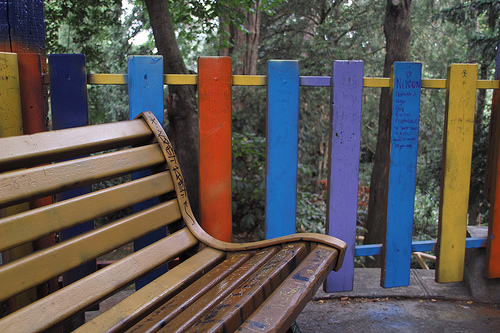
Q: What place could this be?
A: It is a patio.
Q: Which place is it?
A: It is a patio.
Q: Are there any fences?
A: Yes, there is a fence.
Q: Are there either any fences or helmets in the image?
A: Yes, there is a fence.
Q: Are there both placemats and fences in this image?
A: No, there is a fence but no placemats.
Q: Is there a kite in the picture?
A: No, there are no kites.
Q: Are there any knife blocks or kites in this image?
A: No, there are no kites or knife blocks.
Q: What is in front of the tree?
A: The fence is in front of the tree.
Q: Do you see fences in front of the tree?
A: Yes, there is a fence in front of the tree.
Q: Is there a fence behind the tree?
A: No, the fence is in front of the tree.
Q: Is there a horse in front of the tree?
A: No, there is a fence in front of the tree.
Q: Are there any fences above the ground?
A: Yes, there is a fence above the ground.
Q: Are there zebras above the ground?
A: No, there is a fence above the ground.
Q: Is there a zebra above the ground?
A: No, there is a fence above the ground.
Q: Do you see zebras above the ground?
A: No, there is a fence above the ground.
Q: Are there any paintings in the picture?
A: No, there are no paintings.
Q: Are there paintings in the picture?
A: No, there are no paintings.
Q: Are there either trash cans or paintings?
A: No, there are no paintings or trash cans.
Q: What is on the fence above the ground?
A: The graffiti is on the fence.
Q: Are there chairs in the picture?
A: No, there are no chairs.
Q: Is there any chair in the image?
A: No, there are no chairs.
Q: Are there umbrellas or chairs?
A: No, there are no chairs or umbrellas.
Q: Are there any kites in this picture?
A: No, there are no kites.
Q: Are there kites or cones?
A: No, there are no kites or cones.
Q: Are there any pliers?
A: No, there are no pliers.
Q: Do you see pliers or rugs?
A: No, there are no pliers or rugs.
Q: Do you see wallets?
A: No, there are no wallets.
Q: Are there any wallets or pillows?
A: No, there are no wallets or pillows.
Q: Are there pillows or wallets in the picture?
A: No, there are no wallets or pillows.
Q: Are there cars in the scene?
A: No, there are no cars.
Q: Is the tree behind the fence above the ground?
A: Yes, the tree is behind the fence.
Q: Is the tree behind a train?
A: No, the tree is behind the fence.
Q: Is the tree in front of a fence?
A: No, the tree is behind a fence.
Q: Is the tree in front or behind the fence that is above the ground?
A: The tree is behind the fence.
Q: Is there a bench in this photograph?
A: Yes, there is a bench.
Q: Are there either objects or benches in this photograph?
A: Yes, there is a bench.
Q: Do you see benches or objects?
A: Yes, there is a bench.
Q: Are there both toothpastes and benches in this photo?
A: No, there is a bench but no toothpastes.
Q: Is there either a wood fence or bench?
A: Yes, there is a wood bench.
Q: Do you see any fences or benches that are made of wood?
A: Yes, the bench is made of wood.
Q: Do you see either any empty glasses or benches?
A: Yes, there is an empty bench.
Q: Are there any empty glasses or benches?
A: Yes, there is an empty bench.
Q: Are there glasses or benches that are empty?
A: Yes, the bench is empty.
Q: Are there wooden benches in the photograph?
A: Yes, there is a wood bench.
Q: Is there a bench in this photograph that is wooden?
A: Yes, there is a bench that is wooden.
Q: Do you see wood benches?
A: Yes, there is a bench that is made of wood.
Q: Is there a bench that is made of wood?
A: Yes, there is a bench that is made of wood.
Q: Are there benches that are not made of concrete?
A: Yes, there is a bench that is made of wood.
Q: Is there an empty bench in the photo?
A: Yes, there is an empty bench.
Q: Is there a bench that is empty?
A: Yes, there is a bench that is empty.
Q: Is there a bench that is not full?
A: Yes, there is a empty bench.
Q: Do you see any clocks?
A: No, there are no clocks.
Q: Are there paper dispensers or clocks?
A: No, there are no clocks or paper dispensers.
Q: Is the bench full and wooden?
A: No, the bench is wooden but empty.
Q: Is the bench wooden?
A: Yes, the bench is wooden.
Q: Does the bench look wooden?
A: Yes, the bench is wooden.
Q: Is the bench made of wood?
A: Yes, the bench is made of wood.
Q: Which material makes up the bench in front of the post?
A: The bench is made of wood.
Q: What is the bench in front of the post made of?
A: The bench is made of wood.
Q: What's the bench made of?
A: The bench is made of wood.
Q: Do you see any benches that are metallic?
A: No, there is a bench but it is wooden.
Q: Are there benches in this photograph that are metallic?
A: No, there is a bench but it is wooden.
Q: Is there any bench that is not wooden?
A: No, there is a bench but it is wooden.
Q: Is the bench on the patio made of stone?
A: No, the bench is made of wood.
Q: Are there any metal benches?
A: No, there is a bench but it is made of wood.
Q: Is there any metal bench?
A: No, there is a bench but it is made of wood.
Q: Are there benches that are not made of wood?
A: No, there is a bench but it is made of wood.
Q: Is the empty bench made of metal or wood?
A: The bench is made of wood.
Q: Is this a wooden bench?
A: Yes, this is a wooden bench.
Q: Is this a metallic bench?
A: No, this is a wooden bench.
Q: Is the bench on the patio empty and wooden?
A: Yes, the bench is empty and wooden.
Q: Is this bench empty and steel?
A: No, the bench is empty but wooden.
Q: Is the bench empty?
A: Yes, the bench is empty.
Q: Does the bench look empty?
A: Yes, the bench is empty.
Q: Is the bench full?
A: No, the bench is empty.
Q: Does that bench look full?
A: No, the bench is empty.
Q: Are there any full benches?
A: No, there is a bench but it is empty.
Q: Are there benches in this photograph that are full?
A: No, there is a bench but it is empty.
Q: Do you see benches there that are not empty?
A: No, there is a bench but it is empty.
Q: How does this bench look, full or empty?
A: The bench is empty.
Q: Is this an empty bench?
A: Yes, this is an empty bench.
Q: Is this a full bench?
A: No, this is an empty bench.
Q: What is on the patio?
A: The bench is on the patio.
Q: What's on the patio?
A: The bench is on the patio.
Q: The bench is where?
A: The bench is on the patio.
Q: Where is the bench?
A: The bench is on the patio.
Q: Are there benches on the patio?
A: Yes, there is a bench on the patio.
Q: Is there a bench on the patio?
A: Yes, there is a bench on the patio.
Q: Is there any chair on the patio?
A: No, there is a bench on the patio.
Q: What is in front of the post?
A: The bench is in front of the post.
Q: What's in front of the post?
A: The bench is in front of the post.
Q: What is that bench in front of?
A: The bench is in front of the post.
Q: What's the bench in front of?
A: The bench is in front of the post.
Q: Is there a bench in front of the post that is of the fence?
A: Yes, there is a bench in front of the post.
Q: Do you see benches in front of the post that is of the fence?
A: Yes, there is a bench in front of the post.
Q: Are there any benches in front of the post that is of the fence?
A: Yes, there is a bench in front of the post.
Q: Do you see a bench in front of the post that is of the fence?
A: Yes, there is a bench in front of the post.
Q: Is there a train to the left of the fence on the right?
A: No, there is a bench to the left of the fence.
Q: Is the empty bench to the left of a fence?
A: Yes, the bench is to the left of a fence.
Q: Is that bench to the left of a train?
A: No, the bench is to the left of a fence.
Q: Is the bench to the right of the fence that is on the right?
A: No, the bench is to the left of the fence.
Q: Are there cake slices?
A: No, there are no cake slices.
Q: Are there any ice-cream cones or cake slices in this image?
A: No, there are no cake slices or ice-cream cones.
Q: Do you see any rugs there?
A: No, there are no rugs.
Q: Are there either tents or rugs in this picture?
A: No, there are no rugs or tents.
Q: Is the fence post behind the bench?
A: Yes, the post is behind the bench.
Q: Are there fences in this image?
A: Yes, there is a fence.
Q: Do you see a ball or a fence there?
A: Yes, there is a fence.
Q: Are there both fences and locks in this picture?
A: No, there is a fence but no locks.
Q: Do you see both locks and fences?
A: No, there is a fence but no locks.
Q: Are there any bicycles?
A: No, there are no bicycles.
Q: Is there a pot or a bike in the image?
A: No, there are no bikes or pots.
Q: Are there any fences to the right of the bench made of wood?
A: Yes, there is a fence to the right of the bench.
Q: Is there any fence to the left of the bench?
A: No, the fence is to the right of the bench.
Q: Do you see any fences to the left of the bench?
A: No, the fence is to the right of the bench.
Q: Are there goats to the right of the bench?
A: No, there is a fence to the right of the bench.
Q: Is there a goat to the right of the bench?
A: No, there is a fence to the right of the bench.